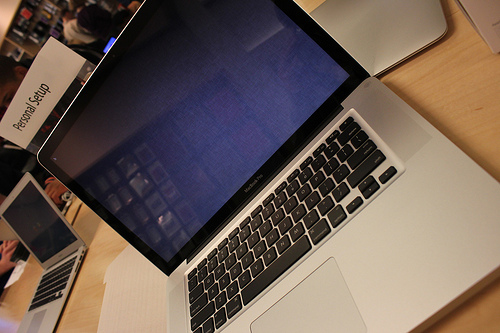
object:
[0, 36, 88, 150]
sign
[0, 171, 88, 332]
laptop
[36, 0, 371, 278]
screen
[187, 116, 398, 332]
black keyboard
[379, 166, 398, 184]
right arrow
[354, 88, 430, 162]
speaker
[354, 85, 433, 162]
grill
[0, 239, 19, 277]
hand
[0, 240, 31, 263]
object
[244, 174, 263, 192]
letters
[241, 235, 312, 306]
space bar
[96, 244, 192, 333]
paper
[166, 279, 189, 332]
speaker grill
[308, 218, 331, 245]
key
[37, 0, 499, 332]
apple-macbook pro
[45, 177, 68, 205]
hands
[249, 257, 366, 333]
pad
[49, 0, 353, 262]
reflection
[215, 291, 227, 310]
z key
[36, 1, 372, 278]
frame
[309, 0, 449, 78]
case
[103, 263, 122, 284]
corner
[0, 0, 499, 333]
surface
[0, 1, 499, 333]
table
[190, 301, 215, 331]
key